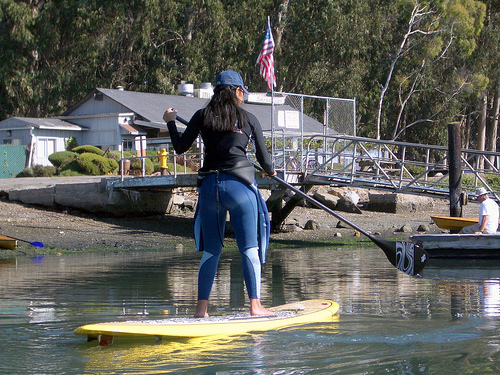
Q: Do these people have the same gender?
A: No, they are both male and female.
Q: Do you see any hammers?
A: No, there are no hammers.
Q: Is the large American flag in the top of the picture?
A: Yes, the American flag is in the top of the image.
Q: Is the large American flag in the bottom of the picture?
A: No, the American flag is in the top of the image.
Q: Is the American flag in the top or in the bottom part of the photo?
A: The American flag is in the top of the image.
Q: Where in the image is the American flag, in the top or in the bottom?
A: The American flag is in the top of the image.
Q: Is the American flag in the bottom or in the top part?
A: The American flag is in the top of the image.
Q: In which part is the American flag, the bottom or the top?
A: The American flag is in the top of the image.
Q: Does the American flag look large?
A: Yes, the American flag is large.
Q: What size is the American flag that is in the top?
A: The American flag is large.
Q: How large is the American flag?
A: The American flag is large.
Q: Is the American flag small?
A: No, the American flag is large.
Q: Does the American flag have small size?
A: No, the American flag is large.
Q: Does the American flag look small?
A: No, the American flag is large.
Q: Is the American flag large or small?
A: The American flag is large.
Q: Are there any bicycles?
A: No, there are no bicycles.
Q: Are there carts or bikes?
A: No, there are no bikes or carts.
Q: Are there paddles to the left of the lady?
A: Yes, there is a paddle to the left of the lady.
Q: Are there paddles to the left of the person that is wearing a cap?
A: Yes, there is a paddle to the left of the lady.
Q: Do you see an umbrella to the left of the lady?
A: No, there is a paddle to the left of the lady.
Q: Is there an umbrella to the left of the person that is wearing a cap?
A: No, there is a paddle to the left of the lady.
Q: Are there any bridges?
A: Yes, there is a bridge.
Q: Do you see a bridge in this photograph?
A: Yes, there is a bridge.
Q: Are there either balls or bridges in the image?
A: Yes, there is a bridge.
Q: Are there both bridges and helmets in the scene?
A: No, there is a bridge but no helmets.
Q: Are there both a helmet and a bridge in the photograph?
A: No, there is a bridge but no helmets.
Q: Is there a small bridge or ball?
A: Yes, there is a small bridge.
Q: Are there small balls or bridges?
A: Yes, there is a small bridge.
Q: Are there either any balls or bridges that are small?
A: Yes, the bridge is small.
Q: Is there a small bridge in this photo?
A: Yes, there is a small bridge.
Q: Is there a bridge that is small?
A: Yes, there is a bridge that is small.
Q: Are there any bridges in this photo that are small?
A: Yes, there is a bridge that is small.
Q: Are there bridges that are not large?
A: Yes, there is a small bridge.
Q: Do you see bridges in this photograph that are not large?
A: Yes, there is a small bridge.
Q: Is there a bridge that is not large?
A: Yes, there is a small bridge.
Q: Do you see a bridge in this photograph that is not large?
A: Yes, there is a small bridge.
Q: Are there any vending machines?
A: No, there are no vending machines.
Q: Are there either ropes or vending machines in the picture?
A: No, there are no vending machines or ropes.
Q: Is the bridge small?
A: Yes, the bridge is small.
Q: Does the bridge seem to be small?
A: Yes, the bridge is small.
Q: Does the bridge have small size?
A: Yes, the bridge is small.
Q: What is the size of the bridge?
A: The bridge is small.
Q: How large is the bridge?
A: The bridge is small.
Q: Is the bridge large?
A: No, the bridge is small.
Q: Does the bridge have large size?
A: No, the bridge is small.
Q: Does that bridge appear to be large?
A: No, the bridge is small.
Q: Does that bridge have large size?
A: No, the bridge is small.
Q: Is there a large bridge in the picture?
A: No, there is a bridge but it is small.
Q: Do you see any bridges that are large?
A: No, there is a bridge but it is small.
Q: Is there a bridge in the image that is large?
A: No, there is a bridge but it is small.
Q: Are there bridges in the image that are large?
A: No, there is a bridge but it is small.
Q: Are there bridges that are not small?
A: No, there is a bridge but it is small.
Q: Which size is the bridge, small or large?
A: The bridge is small.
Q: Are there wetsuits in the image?
A: Yes, there is a wetsuit.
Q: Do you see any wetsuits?
A: Yes, there is a wetsuit.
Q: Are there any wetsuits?
A: Yes, there is a wetsuit.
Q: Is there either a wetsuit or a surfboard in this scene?
A: Yes, there is a wetsuit.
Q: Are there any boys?
A: No, there are no boys.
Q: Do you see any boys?
A: No, there are no boys.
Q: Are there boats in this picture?
A: Yes, there is a boat.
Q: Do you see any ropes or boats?
A: Yes, there is a boat.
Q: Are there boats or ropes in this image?
A: Yes, there is a boat.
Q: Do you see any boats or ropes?
A: Yes, there is a boat.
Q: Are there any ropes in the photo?
A: No, there are no ropes.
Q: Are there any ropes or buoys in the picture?
A: No, there are no ropes or buoys.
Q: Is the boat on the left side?
A: No, the boat is on the right of the image.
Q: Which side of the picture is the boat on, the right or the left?
A: The boat is on the right of the image.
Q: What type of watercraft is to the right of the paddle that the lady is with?
A: The watercraft is a boat.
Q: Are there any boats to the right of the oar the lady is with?
A: Yes, there is a boat to the right of the oar.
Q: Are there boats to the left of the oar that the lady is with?
A: No, the boat is to the right of the oar.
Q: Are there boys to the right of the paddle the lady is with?
A: No, there is a boat to the right of the paddle.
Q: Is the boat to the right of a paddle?
A: Yes, the boat is to the right of a paddle.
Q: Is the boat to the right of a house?
A: No, the boat is to the right of a paddle.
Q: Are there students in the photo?
A: No, there are no students.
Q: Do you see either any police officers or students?
A: No, there are no students or police officers.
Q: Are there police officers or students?
A: No, there are no students or police officers.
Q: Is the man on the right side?
A: Yes, the man is on the right of the image.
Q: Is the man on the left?
A: No, the man is on the right of the image.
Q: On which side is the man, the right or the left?
A: The man is on the right of the image.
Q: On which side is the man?
A: The man is on the right of the image.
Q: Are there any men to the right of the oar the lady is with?
A: Yes, there is a man to the right of the oar.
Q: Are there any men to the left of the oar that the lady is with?
A: No, the man is to the right of the oar.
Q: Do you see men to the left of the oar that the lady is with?
A: No, the man is to the right of the oar.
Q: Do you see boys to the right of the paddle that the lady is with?
A: No, there is a man to the right of the oar.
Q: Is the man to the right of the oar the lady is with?
A: Yes, the man is to the right of the oar.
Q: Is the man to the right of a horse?
A: No, the man is to the right of the oar.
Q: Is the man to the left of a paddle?
A: No, the man is to the right of a paddle.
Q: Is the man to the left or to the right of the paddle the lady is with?
A: The man is to the right of the oar.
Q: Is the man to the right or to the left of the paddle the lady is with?
A: The man is to the right of the oar.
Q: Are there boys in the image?
A: No, there are no boys.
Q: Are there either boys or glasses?
A: No, there are no boys or glasses.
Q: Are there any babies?
A: No, there are no babies.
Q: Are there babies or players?
A: No, there are no babies or players.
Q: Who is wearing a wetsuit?
A: The lady is wearing a wetsuit.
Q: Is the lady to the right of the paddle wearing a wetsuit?
A: Yes, the lady is wearing a wetsuit.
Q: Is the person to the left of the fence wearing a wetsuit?
A: Yes, the lady is wearing a wetsuit.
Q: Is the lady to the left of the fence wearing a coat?
A: No, the lady is wearing a wetsuit.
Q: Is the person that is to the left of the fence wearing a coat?
A: No, the lady is wearing a wetsuit.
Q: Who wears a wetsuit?
A: The lady wears a wetsuit.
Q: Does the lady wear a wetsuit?
A: Yes, the lady wears a wetsuit.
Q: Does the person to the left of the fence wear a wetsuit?
A: Yes, the lady wears a wetsuit.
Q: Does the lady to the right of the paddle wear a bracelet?
A: No, the lady wears a wetsuit.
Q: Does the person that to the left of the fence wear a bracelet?
A: No, the lady wears a wetsuit.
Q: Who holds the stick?
A: The lady holds the stick.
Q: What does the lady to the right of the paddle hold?
A: The lady holds the stick.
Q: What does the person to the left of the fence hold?
A: The lady holds the stick.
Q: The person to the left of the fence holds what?
A: The lady holds the stick.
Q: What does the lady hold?
A: The lady holds the stick.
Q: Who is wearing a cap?
A: The lady is wearing a cap.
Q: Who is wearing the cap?
A: The lady is wearing a cap.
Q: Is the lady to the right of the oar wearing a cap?
A: Yes, the lady is wearing a cap.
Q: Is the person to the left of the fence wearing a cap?
A: Yes, the lady is wearing a cap.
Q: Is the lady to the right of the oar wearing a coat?
A: No, the lady is wearing a cap.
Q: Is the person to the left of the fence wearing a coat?
A: No, the lady is wearing a cap.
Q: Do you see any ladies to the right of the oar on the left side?
A: Yes, there is a lady to the right of the paddle.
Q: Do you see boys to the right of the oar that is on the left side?
A: No, there is a lady to the right of the oar.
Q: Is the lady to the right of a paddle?
A: Yes, the lady is to the right of a paddle.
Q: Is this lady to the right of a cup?
A: No, the lady is to the right of a paddle.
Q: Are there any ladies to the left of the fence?
A: Yes, there is a lady to the left of the fence.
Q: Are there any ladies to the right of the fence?
A: No, the lady is to the left of the fence.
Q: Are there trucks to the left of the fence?
A: No, there is a lady to the left of the fence.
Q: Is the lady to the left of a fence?
A: Yes, the lady is to the left of a fence.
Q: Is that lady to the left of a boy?
A: No, the lady is to the left of a fence.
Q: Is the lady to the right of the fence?
A: No, the lady is to the left of the fence.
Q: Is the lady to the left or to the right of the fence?
A: The lady is to the left of the fence.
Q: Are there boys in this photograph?
A: No, there are no boys.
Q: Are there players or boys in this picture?
A: No, there are no boys or players.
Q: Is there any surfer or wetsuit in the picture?
A: Yes, there is a wetsuit.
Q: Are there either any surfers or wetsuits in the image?
A: Yes, there is a wetsuit.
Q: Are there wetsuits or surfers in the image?
A: Yes, there is a wetsuit.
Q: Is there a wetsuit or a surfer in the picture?
A: Yes, there is a wetsuit.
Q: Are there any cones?
A: No, there are no cones.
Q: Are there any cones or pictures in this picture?
A: No, there are no cones or pictures.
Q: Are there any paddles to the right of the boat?
A: No, the paddle is to the left of the boat.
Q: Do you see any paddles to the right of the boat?
A: No, the paddle is to the left of the boat.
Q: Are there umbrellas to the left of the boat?
A: No, there is a paddle to the left of the boat.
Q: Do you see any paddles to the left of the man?
A: Yes, there is a paddle to the left of the man.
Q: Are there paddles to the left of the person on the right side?
A: Yes, there is a paddle to the left of the man.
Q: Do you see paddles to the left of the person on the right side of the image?
A: Yes, there is a paddle to the left of the man.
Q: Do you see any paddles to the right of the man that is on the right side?
A: No, the paddle is to the left of the man.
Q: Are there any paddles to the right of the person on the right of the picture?
A: No, the paddle is to the left of the man.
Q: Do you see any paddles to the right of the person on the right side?
A: No, the paddle is to the left of the man.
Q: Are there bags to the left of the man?
A: No, there is a paddle to the left of the man.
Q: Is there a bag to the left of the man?
A: No, there is a paddle to the left of the man.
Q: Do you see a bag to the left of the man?
A: No, there is a paddle to the left of the man.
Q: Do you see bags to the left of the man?
A: No, there is a paddle to the left of the man.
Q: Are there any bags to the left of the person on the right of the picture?
A: No, there is a paddle to the left of the man.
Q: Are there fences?
A: Yes, there is a fence.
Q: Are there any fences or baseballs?
A: Yes, there is a fence.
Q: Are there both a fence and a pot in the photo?
A: No, there is a fence but no pots.